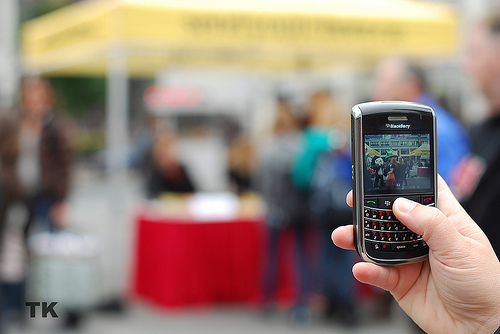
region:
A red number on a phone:
[369, 208, 376, 218]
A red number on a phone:
[376, 207, 383, 217]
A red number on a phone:
[383, 210, 394, 216]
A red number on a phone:
[369, 220, 379, 227]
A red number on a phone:
[378, 218, 384, 228]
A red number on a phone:
[385, 221, 391, 228]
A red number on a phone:
[369, 228, 376, 235]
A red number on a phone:
[376, 230, 385, 237]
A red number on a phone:
[383, 230, 391, 237]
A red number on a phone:
[381, 238, 391, 248]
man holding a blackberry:
[298, 66, 465, 276]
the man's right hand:
[301, 122, 491, 312]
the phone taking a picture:
[345, 104, 449, 267]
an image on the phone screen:
[363, 127, 433, 193]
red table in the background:
[90, 171, 305, 306]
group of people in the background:
[128, 95, 385, 250]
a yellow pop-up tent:
[16, 3, 463, 140]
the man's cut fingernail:
[391, 188, 426, 238]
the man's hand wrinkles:
[390, 215, 492, 314]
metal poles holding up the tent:
[87, 31, 142, 309]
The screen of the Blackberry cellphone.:
[363, 132, 431, 187]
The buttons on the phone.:
[364, 194, 437, 253]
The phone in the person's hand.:
[360, 98, 437, 258]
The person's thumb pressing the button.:
[391, 194, 457, 254]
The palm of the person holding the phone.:
[361, 220, 487, 332]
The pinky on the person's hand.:
[352, 248, 405, 290]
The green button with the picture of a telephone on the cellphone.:
[362, 192, 379, 207]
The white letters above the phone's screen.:
[377, 117, 416, 132]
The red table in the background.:
[131, 213, 298, 308]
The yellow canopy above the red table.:
[26, 6, 478, 69]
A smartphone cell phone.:
[338, 63, 462, 268]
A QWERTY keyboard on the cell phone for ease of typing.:
[352, 194, 453, 247]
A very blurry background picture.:
[9, 1, 496, 301]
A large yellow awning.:
[2, 2, 455, 107]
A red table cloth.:
[138, 197, 291, 313]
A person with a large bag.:
[12, 70, 92, 309]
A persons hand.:
[321, 148, 496, 332]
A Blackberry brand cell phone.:
[371, 111, 420, 140]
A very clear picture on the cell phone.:
[351, 126, 443, 194]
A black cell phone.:
[350, 82, 459, 273]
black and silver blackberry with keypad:
[343, 94, 445, 270]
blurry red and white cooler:
[131, 191, 272, 306]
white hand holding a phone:
[339, 168, 499, 316]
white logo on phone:
[384, 120, 417, 127]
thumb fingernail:
[393, 192, 420, 218]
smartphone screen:
[365, 136, 432, 194]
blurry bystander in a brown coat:
[4, 72, 84, 183]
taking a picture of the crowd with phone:
[137, 73, 477, 291]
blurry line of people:
[257, 84, 344, 272]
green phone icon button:
[363, 197, 380, 211]